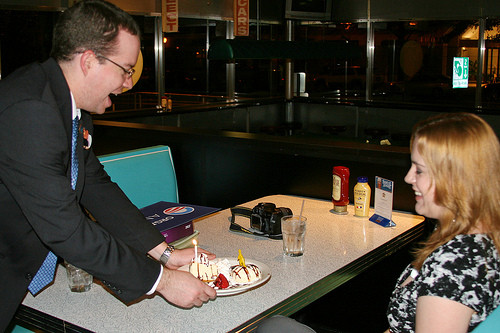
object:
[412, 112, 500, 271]
hair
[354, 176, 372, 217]
bottle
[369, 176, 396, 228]
menu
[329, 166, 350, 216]
bottle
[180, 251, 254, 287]
desert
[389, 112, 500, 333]
woman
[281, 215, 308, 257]
glass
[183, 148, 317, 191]
ground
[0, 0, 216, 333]
man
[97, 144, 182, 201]
vinyl seat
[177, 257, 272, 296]
plate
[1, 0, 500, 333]
celebration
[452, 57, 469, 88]
sign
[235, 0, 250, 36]
sign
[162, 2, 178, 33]
sign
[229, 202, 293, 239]
camera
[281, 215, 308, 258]
drink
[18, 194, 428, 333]
table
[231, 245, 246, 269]
candle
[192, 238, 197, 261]
candle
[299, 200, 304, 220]
straw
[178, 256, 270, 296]
cake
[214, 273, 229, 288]
strawberry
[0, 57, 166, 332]
suit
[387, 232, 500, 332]
top